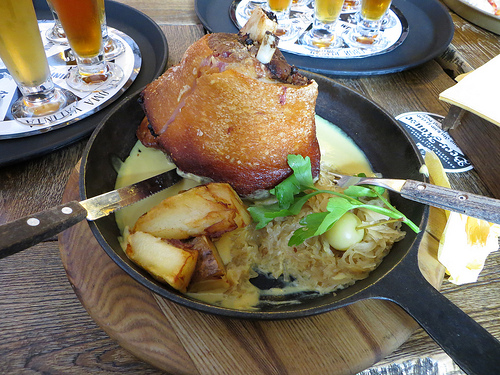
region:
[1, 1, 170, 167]
Beer sitting on tray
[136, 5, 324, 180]
Shank of meat in skillet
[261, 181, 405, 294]
Sauerkraut sitting in the skillet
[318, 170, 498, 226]
Fork resting in sauce in skillet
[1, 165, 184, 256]
Knife resting in sauce on side of skillet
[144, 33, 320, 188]
Crispy skin on top of meat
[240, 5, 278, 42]
Bone sticking out of the top of meat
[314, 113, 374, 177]
Yellow sauce inside skillet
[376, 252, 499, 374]
Handle on side of skillet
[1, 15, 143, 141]
Paper insert with writing on top of tray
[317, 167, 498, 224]
Fork on black pan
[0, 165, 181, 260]
Knife sitting on black pan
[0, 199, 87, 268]
Brown handle on knife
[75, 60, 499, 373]
Black pan on wooden board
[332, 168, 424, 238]
Green leaf under fork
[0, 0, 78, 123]
Glass on black tray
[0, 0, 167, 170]
Black tray on wooden table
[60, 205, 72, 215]
Small silver circle on knife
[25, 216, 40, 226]
Small silver circle on knife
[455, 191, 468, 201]
Small silver screw on fork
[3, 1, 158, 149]
two drinks are on a round tray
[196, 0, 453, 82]
drinks are on a serving tray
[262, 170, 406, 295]
sauerkraut is on a pan with parsley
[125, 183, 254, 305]
cut potatoes are on the pan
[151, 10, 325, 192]
a ham hock is next to the vegetables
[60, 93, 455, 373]
the pan is on a round wood board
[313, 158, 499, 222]
a wooden handled fork is in the pan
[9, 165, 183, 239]
a serrated knife is in the pan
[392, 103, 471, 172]
a coaster is next to the board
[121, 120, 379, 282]
a cream sauce is on the bottom of the dish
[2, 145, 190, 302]
knife on the pan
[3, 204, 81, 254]
dark brown handle of knife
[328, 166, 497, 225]
fork on the pan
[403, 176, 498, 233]
handle of the fork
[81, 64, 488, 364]
black pan food is in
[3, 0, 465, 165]
drinks on two black platters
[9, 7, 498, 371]
wood table plates and pan are on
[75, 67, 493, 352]
black skillet on the table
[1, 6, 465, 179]
two black platters on the wood table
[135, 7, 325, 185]
hunk of meat on black pan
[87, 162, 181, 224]
the blade of the knife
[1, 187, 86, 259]
the hanndle of the knife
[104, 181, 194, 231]
the seratted edge of the kinfe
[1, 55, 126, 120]
the base of the glasses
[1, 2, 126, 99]
the beer glasses on the trey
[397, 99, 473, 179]
the coaster on the table top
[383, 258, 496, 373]
the black handle of the pan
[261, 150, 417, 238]
the parsley on the pan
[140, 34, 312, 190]
the burger in the pan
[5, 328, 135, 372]
the rings on the wooden table top